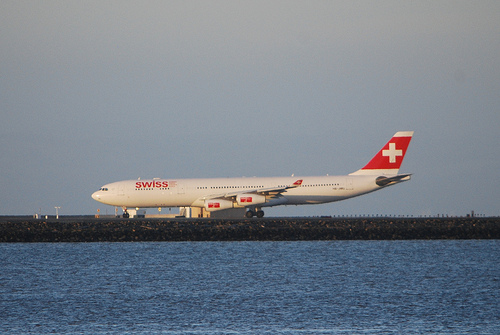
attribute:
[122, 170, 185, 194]
letter — red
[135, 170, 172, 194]
letter — red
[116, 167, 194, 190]
letters — red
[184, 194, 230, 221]
decal — red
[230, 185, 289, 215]
decal — red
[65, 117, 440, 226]
airliner — white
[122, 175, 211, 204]
swiss — written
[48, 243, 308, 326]
water — foreground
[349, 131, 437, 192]
tail — red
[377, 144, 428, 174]
cross — white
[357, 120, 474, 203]
tail — red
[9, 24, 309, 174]
sky — blue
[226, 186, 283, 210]
engine — large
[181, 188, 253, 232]
engine — large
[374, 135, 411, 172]
cross — white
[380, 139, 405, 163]
cross — white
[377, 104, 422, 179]
background — red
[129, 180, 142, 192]
letter — red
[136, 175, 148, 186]
letter — red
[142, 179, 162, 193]
letter — red